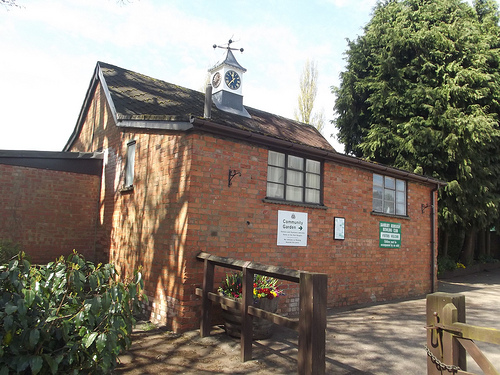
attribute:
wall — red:
[183, 134, 431, 330]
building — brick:
[3, 55, 448, 332]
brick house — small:
[188, 106, 482, 353]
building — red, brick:
[127, 93, 418, 255]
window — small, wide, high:
[254, 152, 334, 212]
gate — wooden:
[425, 288, 499, 374]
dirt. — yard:
[354, 301, 401, 366]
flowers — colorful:
[259, 276, 282, 299]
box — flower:
[206, 265, 299, 346]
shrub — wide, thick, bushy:
[3, 252, 133, 373]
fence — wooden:
[193, 249, 499, 373]